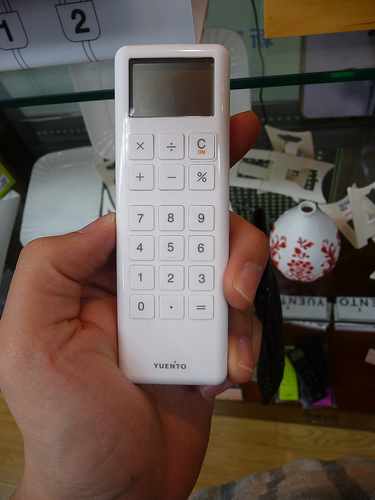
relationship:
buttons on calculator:
[126, 132, 218, 329] [100, 40, 232, 394]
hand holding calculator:
[10, 114, 263, 498] [100, 40, 232, 394]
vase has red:
[265, 188, 342, 285] [291, 241, 312, 257]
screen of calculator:
[128, 59, 214, 114] [100, 40, 232, 394]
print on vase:
[267, 227, 335, 276] [265, 188, 342, 285]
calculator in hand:
[100, 40, 232, 394] [10, 114, 263, 498]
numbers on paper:
[4, 10, 90, 46] [70, 4, 192, 62]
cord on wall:
[244, 3, 273, 115] [7, 3, 364, 124]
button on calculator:
[159, 133, 185, 159] [100, 40, 232, 394]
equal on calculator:
[193, 293, 214, 325] [100, 40, 232, 394]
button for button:
[182, 130, 220, 164] [188, 131, 217, 162]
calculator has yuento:
[100, 40, 232, 394] [148, 356, 195, 377]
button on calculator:
[158, 198, 185, 238] [100, 40, 232, 394]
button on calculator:
[128, 203, 157, 235] [100, 40, 232, 394]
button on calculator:
[132, 138, 153, 157] [100, 40, 232, 394]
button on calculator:
[129, 166, 152, 189] [100, 40, 232, 394]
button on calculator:
[159, 162, 186, 195] [100, 40, 232, 394]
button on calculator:
[188, 164, 214, 190] [100, 40, 232, 394]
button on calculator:
[128, 236, 156, 261] [100, 40, 232, 394]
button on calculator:
[157, 235, 184, 264] [100, 40, 232, 394]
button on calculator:
[187, 231, 219, 264] [100, 40, 232, 394]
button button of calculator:
[188, 131, 217, 162] [100, 40, 232, 394]